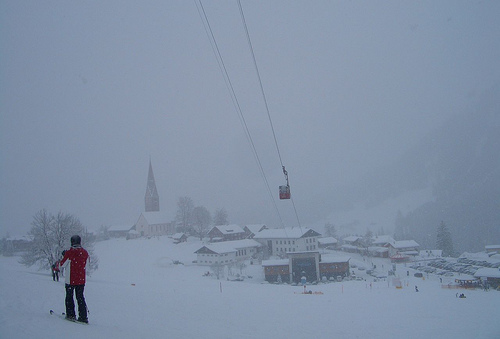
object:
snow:
[0, 80, 496, 339]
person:
[51, 234, 91, 323]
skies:
[49, 309, 90, 326]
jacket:
[61, 247, 90, 288]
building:
[260, 250, 351, 286]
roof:
[320, 254, 351, 263]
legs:
[64, 284, 76, 319]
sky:
[3, 2, 499, 223]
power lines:
[234, 0, 306, 227]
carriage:
[278, 184, 291, 199]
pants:
[63, 283, 88, 320]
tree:
[16, 206, 98, 279]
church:
[144, 155, 160, 213]